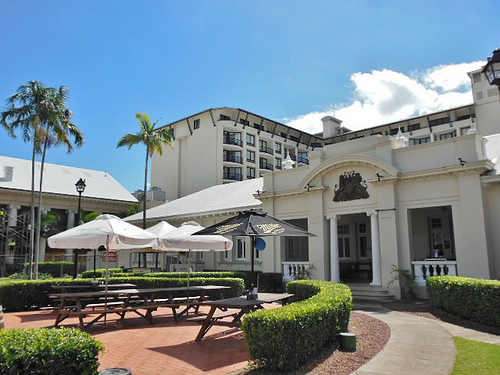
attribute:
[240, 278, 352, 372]
leaves — green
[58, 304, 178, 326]
bench — wooden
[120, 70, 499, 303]
building — tall, white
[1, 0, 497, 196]
sky — blue, clear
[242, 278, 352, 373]
hedge — well-trimmed, green, well trimmed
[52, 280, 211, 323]
benches — empty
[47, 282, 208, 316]
benches — wooden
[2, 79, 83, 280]
palm tree — green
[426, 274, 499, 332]
hedge — well-trimmed, green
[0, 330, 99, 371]
hedge — well-trimmed, green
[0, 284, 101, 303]
hedge — well-trimmed, green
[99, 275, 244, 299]
hedge — well-trimmed, green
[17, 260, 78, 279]
hedge — well-trimmed, green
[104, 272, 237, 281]
hedge — well-trimmed, green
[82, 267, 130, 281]
hedge — well-trimmed, green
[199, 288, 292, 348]
table — wooden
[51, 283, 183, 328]
table — wooden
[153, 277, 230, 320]
table — wooden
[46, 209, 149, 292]
umbrella — open, white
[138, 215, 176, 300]
umbrella — open, white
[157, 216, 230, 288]
umbrella — open, white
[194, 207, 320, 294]
umbrella — open, black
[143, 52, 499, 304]
building — tall, white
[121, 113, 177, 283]
tree — tall, palm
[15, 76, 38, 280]
tree — tall, palm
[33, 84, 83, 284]
tree — tall, palm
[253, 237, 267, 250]
balloon — blue, hanging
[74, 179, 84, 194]
lamp — old-fashioned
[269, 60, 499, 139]
cloud — white, bright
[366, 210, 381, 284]
column — white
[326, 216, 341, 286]
column — white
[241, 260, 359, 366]
fence — green